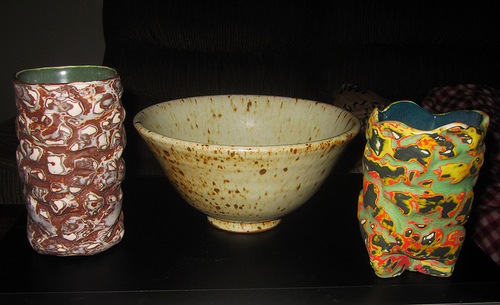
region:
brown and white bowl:
[133, 78, 364, 253]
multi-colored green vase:
[353, 96, 492, 291]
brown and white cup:
[6, 64, 136, 259]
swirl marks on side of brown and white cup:
[37, 120, 84, 185]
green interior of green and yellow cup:
[399, 109, 446, 128]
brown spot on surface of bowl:
[255, 163, 271, 184]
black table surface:
[2, 172, 496, 303]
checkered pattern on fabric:
[424, 82, 498, 274]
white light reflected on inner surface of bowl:
[239, 112, 264, 136]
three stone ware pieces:
[11, 67, 490, 279]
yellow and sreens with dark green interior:
[357, 92, 488, 277]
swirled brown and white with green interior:
[15, 55, 127, 255]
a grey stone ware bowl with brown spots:
[135, 68, 358, 228]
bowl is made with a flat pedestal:
[203, 217, 280, 232]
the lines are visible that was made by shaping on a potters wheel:
[147, 141, 337, 196]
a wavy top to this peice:
[365, 95, 485, 170]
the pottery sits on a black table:
[2, 191, 475, 303]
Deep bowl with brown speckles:
[130, 90, 362, 233]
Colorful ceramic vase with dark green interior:
[355, 96, 491, 280]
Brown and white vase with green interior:
[11, 63, 128, 258]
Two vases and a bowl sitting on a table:
[9, 62, 494, 281]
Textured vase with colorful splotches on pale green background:
[353, 95, 491, 280]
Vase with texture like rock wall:
[10, 62, 128, 258]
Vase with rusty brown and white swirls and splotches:
[10, 62, 129, 258]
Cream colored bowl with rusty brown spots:
[130, 91, 362, 234]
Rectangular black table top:
[1, 170, 498, 302]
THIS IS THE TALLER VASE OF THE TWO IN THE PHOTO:
[5, 52, 127, 262]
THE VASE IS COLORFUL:
[352, 87, 492, 287]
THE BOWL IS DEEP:
[130, 91, 370, 237]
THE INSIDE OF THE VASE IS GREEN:
[7, 57, 120, 100]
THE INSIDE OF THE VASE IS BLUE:
[362, 93, 487, 139]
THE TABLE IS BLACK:
[10, 150, 496, 301]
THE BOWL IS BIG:
[140, 92, 363, 247]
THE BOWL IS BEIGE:
[122, 80, 370, 246]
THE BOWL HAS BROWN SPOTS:
[125, 83, 367, 249]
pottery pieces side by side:
[7, 46, 472, 287]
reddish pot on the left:
[17, 60, 145, 267]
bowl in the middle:
[136, 72, 363, 243]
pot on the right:
[345, 91, 490, 276]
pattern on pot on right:
[390, 157, 450, 214]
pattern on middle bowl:
[195, 153, 270, 193]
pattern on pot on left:
[48, 133, 98, 181]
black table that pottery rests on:
[7, 160, 493, 296]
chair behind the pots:
[85, 3, 316, 193]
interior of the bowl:
[213, 113, 293, 140]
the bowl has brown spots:
[135, 93, 359, 232]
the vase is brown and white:
[15, 63, 125, 253]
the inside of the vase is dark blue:
[358, 101, 488, 277]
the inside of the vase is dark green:
[14, 64, 126, 255]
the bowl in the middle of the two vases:
[12, 65, 489, 276]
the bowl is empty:
[133, 93, 360, 232]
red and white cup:
[14, 50, 131, 260]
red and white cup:
[6, 48, 140, 263]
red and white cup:
[6, 53, 138, 259]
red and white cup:
[7, 54, 142, 259]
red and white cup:
[1, 55, 147, 263]